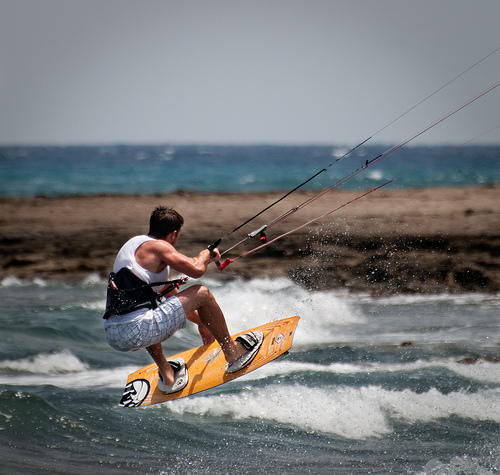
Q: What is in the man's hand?
A: A handle.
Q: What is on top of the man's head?
A: His hair.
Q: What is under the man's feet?
A: A board.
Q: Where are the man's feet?
A: On the board.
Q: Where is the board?
A: In the water.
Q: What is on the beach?
A: Sand.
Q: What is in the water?
A: A man.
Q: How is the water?
A: Wavy.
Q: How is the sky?
A: Clear.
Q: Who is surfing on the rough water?
A: A man.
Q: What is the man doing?
A: Water sports.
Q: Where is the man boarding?
A: The ocean.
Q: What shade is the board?
A: Yellow.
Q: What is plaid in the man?
A: Shorts.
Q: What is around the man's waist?
A: Harness for towing.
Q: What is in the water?
A: Waves.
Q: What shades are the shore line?
A: Blue and brown.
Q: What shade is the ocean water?
A: Blue.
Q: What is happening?
A: Kite surfing.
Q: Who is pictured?
A: Male kite surfer.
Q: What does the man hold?
A: The bar to the kite.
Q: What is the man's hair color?
A: Brunette.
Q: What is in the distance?
A: The ocean blue waters.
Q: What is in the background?
A: A rocky shoreline.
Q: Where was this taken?
A: The ocean.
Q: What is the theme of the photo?
A: Sports and adventure.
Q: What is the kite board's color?
A: Yellow.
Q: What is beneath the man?
A: Cresting waves.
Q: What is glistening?
A: The water.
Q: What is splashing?
A: The water.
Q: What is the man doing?
A: Wind surfing.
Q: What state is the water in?
A: Rambunctious.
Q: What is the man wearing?
A: Shorts.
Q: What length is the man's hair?
A: Short.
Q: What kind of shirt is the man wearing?
A: Tank top.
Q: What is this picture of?
A: A kite boarder.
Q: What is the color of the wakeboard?
A: Yellow.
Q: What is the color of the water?
A: Blue.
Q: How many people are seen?
A: 1.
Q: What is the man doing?
A: Wakeboarding.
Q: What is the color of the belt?
A: Black.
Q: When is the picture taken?
A: Daytime.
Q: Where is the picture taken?
A: At the beach.